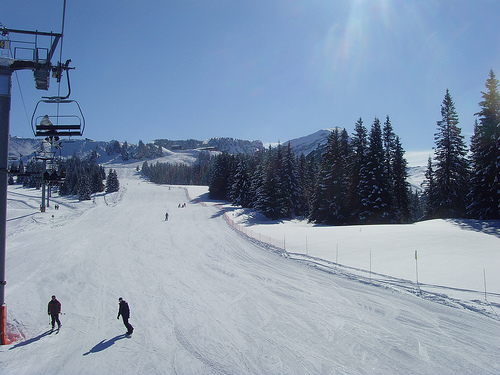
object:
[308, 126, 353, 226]
tree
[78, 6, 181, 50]
sky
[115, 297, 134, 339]
person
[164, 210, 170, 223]
person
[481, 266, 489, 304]
pole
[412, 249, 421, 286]
pole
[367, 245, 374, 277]
pole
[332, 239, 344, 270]
pole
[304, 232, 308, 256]
pole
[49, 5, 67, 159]
cable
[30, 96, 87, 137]
air lift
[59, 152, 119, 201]
trees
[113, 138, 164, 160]
trees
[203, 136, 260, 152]
trees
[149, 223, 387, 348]
slope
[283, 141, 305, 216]
trees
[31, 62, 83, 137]
ski lift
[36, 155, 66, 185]
ski lift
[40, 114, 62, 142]
person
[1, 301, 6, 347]
base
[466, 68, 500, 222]
tree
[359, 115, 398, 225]
trees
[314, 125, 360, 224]
trees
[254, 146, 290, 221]
trees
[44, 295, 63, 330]
people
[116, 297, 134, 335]
people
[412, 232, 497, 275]
snow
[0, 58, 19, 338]
beam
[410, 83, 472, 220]
tree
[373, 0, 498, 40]
sky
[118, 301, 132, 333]
clothing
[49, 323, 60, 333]
skis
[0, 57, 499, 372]
course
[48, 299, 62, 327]
clothes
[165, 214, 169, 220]
clothes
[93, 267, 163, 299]
snow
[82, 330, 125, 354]
shadow